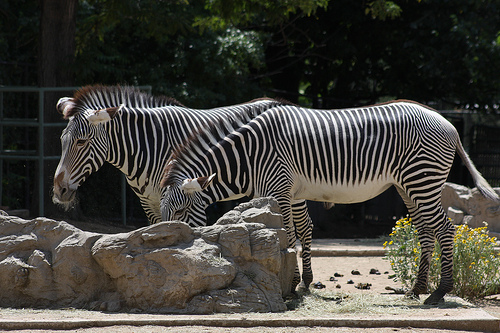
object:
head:
[50, 95, 125, 204]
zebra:
[49, 82, 322, 296]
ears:
[54, 95, 80, 116]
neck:
[109, 103, 163, 178]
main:
[62, 83, 190, 120]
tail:
[453, 140, 500, 204]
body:
[241, 99, 458, 304]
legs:
[407, 188, 458, 293]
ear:
[86, 103, 129, 123]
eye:
[72, 135, 90, 145]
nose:
[50, 178, 71, 201]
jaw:
[69, 181, 82, 199]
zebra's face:
[54, 113, 94, 191]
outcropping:
[0, 195, 293, 314]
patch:
[333, 296, 388, 315]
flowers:
[461, 237, 469, 245]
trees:
[385, 0, 500, 116]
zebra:
[156, 99, 500, 304]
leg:
[291, 199, 317, 285]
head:
[157, 160, 221, 229]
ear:
[179, 171, 217, 195]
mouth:
[52, 187, 80, 205]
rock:
[20, 249, 56, 299]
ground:
[0, 237, 500, 332]